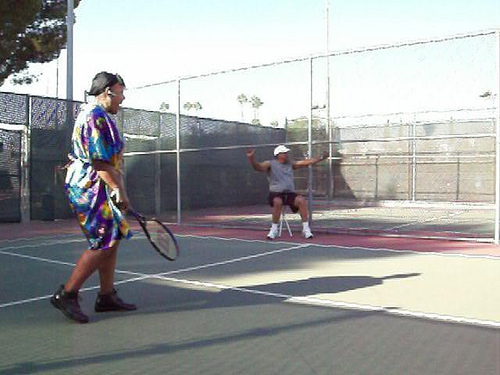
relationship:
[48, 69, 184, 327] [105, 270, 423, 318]
player casting shadow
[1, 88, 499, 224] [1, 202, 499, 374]
fence surrounding court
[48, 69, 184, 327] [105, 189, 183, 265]
player holding racket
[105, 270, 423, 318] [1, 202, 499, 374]
shadow on top of court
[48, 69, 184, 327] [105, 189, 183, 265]
player has racket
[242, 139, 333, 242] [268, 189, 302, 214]
spectator wearing shorts